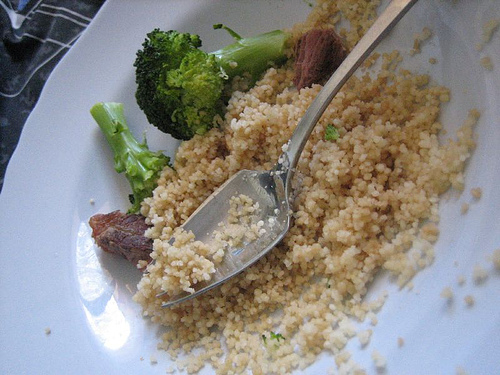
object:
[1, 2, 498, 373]
plate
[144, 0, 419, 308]
spoon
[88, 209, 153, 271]
food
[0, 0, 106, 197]
mat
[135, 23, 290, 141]
broccoli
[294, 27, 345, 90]
steak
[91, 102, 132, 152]
green stem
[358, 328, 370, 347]
cous cous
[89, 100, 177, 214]
vegetable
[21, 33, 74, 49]
stripe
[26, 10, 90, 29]
stripe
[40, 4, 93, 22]
stripe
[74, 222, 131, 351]
light